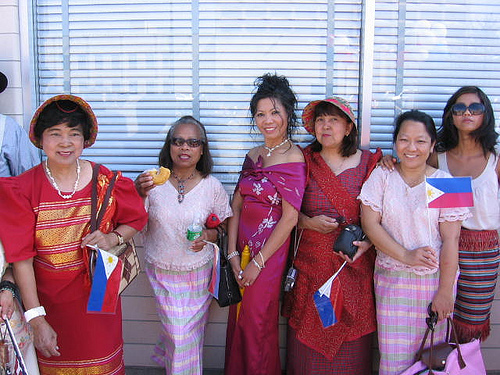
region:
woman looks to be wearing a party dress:
[222, 50, 312, 370]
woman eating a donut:
[128, 104, 248, 350]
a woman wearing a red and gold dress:
[8, 75, 164, 373]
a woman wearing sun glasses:
[429, 68, 490, 163]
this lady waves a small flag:
[352, 79, 481, 306]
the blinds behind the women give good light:
[59, 28, 436, 121]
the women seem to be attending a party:
[23, 79, 490, 191]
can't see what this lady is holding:
[233, 235, 257, 327]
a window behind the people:
[37, 5, 494, 196]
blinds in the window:
[38, 3, 346, 121]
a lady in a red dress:
[12, 83, 135, 373]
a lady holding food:
[144, 115, 218, 372]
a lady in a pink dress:
[235, 85, 300, 372]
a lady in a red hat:
[294, 92, 372, 366]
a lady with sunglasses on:
[446, 85, 491, 169]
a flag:
[426, 175, 476, 206]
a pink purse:
[399, 330, 476, 374]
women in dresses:
[8, 67, 498, 372]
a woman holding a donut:
[134, 159, 174, 196]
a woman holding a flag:
[76, 236, 130, 331]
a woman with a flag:
[366, 104, 477, 345]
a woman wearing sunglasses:
[443, 98, 494, 123]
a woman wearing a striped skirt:
[453, 229, 498, 335]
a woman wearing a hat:
[300, 90, 358, 140]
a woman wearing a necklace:
[38, 156, 88, 202]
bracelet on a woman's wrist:
[222, 249, 241, 261]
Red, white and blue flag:
[82, 238, 128, 321]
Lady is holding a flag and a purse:
[83, 156, 140, 318]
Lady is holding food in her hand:
[136, 166, 173, 193]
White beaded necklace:
[30, 152, 88, 202]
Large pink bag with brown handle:
[392, 318, 492, 373]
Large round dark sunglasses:
[444, 99, 492, 120]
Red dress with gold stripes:
[5, 165, 127, 373]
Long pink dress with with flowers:
[233, 151, 297, 373]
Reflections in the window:
[98, 40, 168, 125]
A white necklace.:
[37, 149, 82, 206]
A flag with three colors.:
[419, 169, 471, 209]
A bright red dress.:
[6, 163, 143, 372]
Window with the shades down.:
[22, 6, 367, 189]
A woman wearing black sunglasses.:
[161, 110, 213, 175]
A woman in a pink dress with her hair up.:
[232, 78, 309, 372]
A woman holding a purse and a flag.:
[371, 107, 471, 372]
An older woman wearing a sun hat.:
[300, 80, 368, 182]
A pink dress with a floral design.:
[220, 155, 299, 372]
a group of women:
[20, 46, 499, 356]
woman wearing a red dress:
[5, 165, 159, 364]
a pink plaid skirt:
[145, 265, 220, 373]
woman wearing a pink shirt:
[135, 168, 223, 277]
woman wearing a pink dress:
[212, 143, 303, 367]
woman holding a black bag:
[326, 210, 370, 262]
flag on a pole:
[394, 159, 482, 274]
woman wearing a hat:
[292, 85, 362, 142]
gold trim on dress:
[29, 190, 107, 264]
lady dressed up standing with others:
[5, 91, 131, 371]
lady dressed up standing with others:
[138, 107, 219, 372]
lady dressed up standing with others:
[220, 72, 295, 362]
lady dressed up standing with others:
[285, 81, 367, 371]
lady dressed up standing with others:
[360, 96, 465, 371]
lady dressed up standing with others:
[430, 76, 491, 366]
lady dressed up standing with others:
[0, 65, 37, 198]